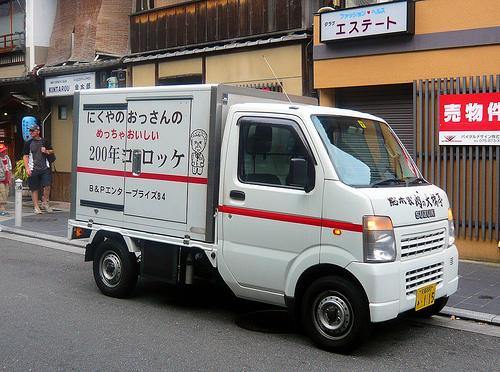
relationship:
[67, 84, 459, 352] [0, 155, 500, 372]
truck on paved street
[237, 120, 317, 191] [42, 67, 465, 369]
front window on truck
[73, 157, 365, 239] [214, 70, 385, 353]
stripe on side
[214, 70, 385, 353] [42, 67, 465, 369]
side of truck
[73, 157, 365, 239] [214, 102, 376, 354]
stripe on side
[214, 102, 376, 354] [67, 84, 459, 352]
side of truck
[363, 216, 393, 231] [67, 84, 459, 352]
front lights on truck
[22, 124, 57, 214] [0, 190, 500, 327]
man walking on concrete sidewalk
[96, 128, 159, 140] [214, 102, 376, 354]
red lettering on side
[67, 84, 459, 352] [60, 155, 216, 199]
truck with stripes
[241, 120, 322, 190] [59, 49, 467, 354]
front window of truck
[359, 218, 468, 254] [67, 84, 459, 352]
front lights of truck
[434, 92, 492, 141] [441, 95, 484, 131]
red sign with lettering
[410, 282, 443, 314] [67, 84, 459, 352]
license plate of truck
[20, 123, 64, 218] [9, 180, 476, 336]
man walking walking sidewalk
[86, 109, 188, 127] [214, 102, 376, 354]
black lettering on side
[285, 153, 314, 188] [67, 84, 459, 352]
sideview mirror on truck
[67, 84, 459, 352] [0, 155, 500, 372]
truck parked on paved street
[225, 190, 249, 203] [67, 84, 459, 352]
black doorhandle of truck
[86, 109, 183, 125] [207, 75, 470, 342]
black lettering on front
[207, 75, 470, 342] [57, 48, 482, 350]
front of vehicle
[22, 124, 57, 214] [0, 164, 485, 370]
man walking walking on sidewalk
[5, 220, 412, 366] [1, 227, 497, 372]
asphalt of road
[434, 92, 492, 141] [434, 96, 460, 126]
red sign with lettering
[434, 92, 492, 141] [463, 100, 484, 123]
red sign with lettering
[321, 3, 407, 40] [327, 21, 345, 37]
sign with lettering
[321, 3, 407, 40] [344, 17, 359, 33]
sign with lettering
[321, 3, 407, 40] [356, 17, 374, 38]
sign with lettering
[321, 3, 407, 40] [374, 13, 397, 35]
sign with lettering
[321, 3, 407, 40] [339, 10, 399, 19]
sign with lettering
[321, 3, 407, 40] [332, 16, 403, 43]
sign with lettering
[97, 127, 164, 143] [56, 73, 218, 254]
red lettering on side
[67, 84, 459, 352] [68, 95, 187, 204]
truck with lettering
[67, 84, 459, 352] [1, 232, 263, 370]
truck on on street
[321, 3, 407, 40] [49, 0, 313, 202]
sign on on bars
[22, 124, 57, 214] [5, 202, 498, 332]
man walking standing on sidewalk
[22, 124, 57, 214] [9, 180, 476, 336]
man walking walking on sidewalk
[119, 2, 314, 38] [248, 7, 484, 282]
bars on building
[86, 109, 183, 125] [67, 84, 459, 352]
black lettering on truck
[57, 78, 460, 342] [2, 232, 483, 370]
truck standing street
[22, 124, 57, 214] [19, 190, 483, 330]
man walking standing sidewalk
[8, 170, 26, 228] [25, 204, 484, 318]
pole in sidewalk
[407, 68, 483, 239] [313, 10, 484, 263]
gate on building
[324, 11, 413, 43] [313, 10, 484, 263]
sign on building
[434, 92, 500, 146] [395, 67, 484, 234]
red sign on gate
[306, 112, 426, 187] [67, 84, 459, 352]
glass windshield on truck